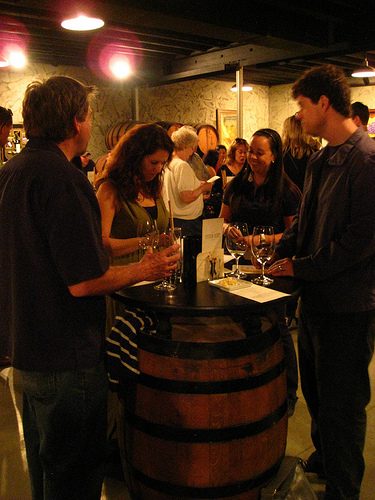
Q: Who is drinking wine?
A: Men and women.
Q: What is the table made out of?
A: A barrel.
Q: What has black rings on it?
A: The barrel table.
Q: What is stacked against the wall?
A: Barrels.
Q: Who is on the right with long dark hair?
A: A woman.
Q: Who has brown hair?
A: The man.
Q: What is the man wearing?
A: A black shirt.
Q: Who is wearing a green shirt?
A: The woman.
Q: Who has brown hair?
A: The woman.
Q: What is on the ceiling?
A: Lights.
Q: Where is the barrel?
A: Between the people.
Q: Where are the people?
A: Around the barrel.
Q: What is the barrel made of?
A: Wood.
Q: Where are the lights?
A: On the ceiling.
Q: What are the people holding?
A: Glasses.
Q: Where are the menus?
A: On the barrel.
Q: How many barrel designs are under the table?
A: 1.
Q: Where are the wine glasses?
A: On the table.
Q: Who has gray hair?
A: The woman with the white shirt.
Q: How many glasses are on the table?
A: 4.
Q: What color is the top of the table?
A: Black.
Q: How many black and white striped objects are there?
A: 1.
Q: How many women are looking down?
A: 1.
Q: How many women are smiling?
A: 1.